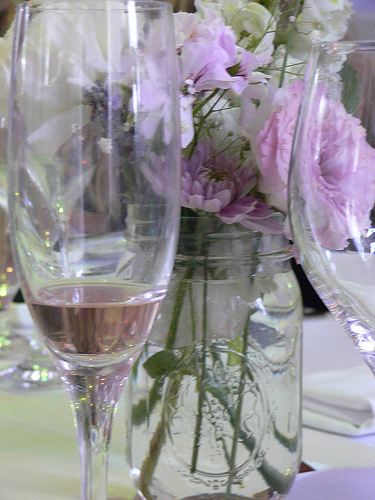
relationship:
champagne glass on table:
[7, 0, 182, 499] [22, 469, 69, 498]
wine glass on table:
[326, 186, 362, 205] [22, 469, 69, 498]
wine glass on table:
[28, 349, 39, 369] [22, 469, 69, 498]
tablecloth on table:
[335, 487, 364, 499] [22, 469, 69, 498]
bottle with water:
[272, 287, 292, 305] [173, 470, 184, 489]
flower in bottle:
[184, 42, 214, 67] [272, 287, 292, 305]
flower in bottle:
[267, 131, 280, 162] [272, 287, 292, 305]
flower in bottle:
[312, 4, 340, 25] [272, 287, 292, 305]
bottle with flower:
[272, 287, 292, 305] [226, 7, 247, 21]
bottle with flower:
[272, 287, 292, 305] [184, 42, 214, 67]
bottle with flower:
[272, 287, 292, 305] [312, 4, 340, 25]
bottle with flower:
[272, 287, 292, 305] [190, 165, 243, 200]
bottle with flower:
[272, 287, 292, 305] [267, 131, 280, 162]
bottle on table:
[272, 287, 292, 305] [22, 469, 69, 498]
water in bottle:
[173, 470, 184, 489] [272, 287, 292, 305]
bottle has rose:
[116, 190, 304, 500] [190, 165, 243, 200]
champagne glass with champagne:
[7, 0, 182, 499] [22, 284, 167, 387]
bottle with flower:
[116, 190, 304, 500] [190, 165, 243, 200]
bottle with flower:
[116, 190, 304, 500] [267, 131, 280, 162]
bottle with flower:
[116, 190, 304, 500] [184, 42, 214, 67]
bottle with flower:
[116, 190, 304, 500] [226, 7, 247, 21]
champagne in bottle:
[29, 280, 168, 363] [116, 190, 304, 500]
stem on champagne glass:
[59, 370, 127, 498] [7, 0, 182, 499]